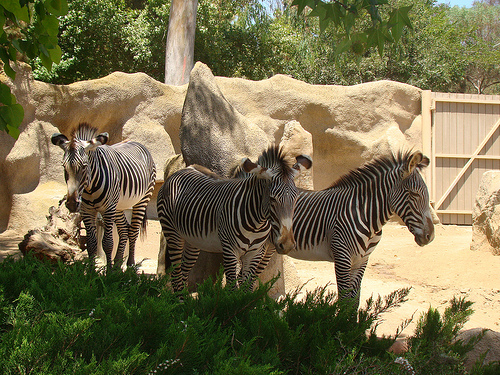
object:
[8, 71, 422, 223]
fence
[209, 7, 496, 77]
trees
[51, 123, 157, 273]
zebra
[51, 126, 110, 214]
head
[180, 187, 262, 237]
stripes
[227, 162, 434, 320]
zebras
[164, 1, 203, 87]
tree trunk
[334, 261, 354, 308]
leg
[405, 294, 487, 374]
shrubbery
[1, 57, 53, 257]
rock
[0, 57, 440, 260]
boulder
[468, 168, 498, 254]
boulder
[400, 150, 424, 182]
zebras ears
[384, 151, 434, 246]
head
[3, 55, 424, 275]
wall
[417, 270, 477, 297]
dirt ground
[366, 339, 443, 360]
trash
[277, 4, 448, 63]
leaves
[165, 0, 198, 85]
tree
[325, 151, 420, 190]
hair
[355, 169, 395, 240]
neck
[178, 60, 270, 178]
rock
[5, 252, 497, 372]
bush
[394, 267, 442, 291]
dirt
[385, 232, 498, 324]
ground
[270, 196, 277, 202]
eye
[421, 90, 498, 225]
fence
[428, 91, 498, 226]
door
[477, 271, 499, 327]
floor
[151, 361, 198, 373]
pine cone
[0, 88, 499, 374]
pen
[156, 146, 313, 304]
zebra